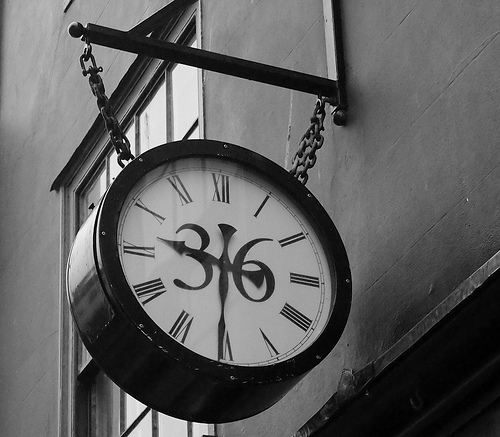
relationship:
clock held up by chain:
[65, 139, 356, 423] [80, 55, 131, 160]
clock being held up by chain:
[65, 139, 356, 423] [288, 105, 328, 184]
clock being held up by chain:
[65, 139, 356, 423] [80, 55, 131, 160]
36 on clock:
[174, 221, 277, 304] [65, 139, 356, 423]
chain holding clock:
[80, 55, 131, 160] [65, 139, 356, 423]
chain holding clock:
[288, 105, 328, 184] [65, 139, 356, 423]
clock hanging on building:
[65, 139, 356, 423] [2, 2, 496, 435]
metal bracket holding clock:
[69, 0, 347, 123] [65, 139, 356, 423]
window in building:
[50, 1, 215, 436] [2, 2, 496, 435]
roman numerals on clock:
[125, 170, 322, 359] [65, 139, 356, 423]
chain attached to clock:
[80, 55, 131, 160] [65, 139, 356, 423]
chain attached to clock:
[288, 105, 328, 184] [65, 139, 356, 423]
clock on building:
[65, 139, 356, 423] [2, 2, 496, 435]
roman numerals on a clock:
[125, 170, 322, 359] [65, 139, 356, 423]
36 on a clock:
[174, 221, 277, 304] [65, 139, 356, 423]